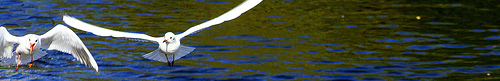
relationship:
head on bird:
[20, 34, 45, 44] [0, 23, 70, 66]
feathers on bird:
[153, 49, 206, 62] [80, 9, 260, 71]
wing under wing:
[34, 14, 80, 78] [66, 9, 122, 46]